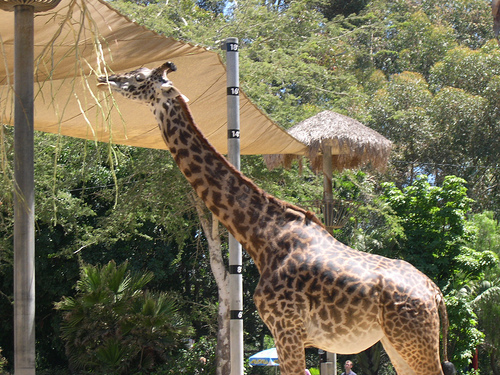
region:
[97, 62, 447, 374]
Giraffe in a zoo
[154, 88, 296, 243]
Long neck of the giraffe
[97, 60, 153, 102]
Head of the giraffe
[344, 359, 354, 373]
Head of a man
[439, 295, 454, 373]
Tail of giraffe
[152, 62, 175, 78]
Horns on giraffe's head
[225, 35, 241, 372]
A pole with markings in feet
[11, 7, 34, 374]
A light pole in the enclosure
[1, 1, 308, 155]
A yellow sun shed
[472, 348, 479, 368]
A part of a red pole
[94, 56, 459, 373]
giraffe eating leaves from a tree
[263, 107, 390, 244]
straw covered umbrella over a giraffe food basket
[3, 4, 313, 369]
canopy in the giraffe exhibit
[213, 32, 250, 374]
silver pole with black feet markers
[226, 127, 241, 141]
the number 14 on a black strip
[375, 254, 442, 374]
the giraffe's hind legs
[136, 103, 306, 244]
the giraffe's neck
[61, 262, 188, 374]
palm trees in the background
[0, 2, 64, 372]
giraffe feeder on a tall metal pole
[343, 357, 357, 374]
a man standing in the distance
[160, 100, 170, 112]
brown spot on giraffe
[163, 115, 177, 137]
brown spot on giraffe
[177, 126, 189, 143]
brown spot on giraffe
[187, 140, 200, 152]
brown spot on giraffe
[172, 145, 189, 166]
brown spot on giraffe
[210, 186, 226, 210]
brown spot on giraffe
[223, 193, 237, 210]
brown spot on giraffe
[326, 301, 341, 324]
brown spot on giraffe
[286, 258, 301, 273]
brown spot on giraffe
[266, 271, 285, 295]
brown spot on giraffe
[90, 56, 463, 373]
Giraffe eating the branch.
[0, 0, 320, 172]
Brown canopy over the giraffe.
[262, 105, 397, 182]
Grass covered canopy.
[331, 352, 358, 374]
Person in the background.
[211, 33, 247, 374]
Metal pole behind the giraffe.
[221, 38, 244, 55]
Measurement on the pole.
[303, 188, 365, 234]
Basket on the pole.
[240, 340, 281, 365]
Blue canopy in the background.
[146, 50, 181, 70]
Horns on the giraffe.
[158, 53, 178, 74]
Black tips on the horns.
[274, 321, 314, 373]
the leg of a giraffe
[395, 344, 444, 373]
the leg of a giraffe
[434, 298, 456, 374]
the tail of a giraffe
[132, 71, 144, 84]
the eye of a giraffe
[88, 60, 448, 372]
a tall giraffe near a tent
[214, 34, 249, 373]
a large metal pole with numbers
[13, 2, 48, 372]
a large metal pole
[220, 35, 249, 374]
a large metal pole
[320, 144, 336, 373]
a large wooden pole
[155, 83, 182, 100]
the ear of a giraffe